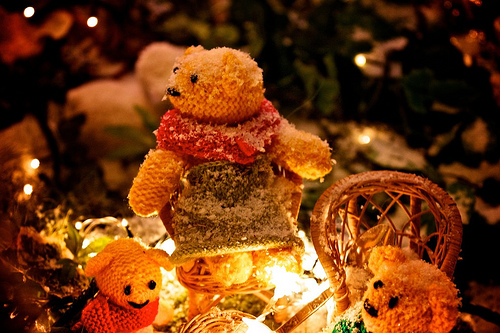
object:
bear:
[76, 239, 176, 332]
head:
[159, 44, 266, 123]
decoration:
[126, 42, 333, 294]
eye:
[173, 66, 179, 74]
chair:
[157, 170, 303, 325]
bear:
[60, 43, 185, 191]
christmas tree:
[269, 15, 499, 200]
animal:
[80, 45, 462, 332]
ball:
[164, 44, 265, 126]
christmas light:
[272, 258, 325, 305]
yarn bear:
[127, 45, 331, 284]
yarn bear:
[323, 244, 463, 333]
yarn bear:
[78, 237, 173, 333]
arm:
[128, 149, 183, 217]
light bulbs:
[22, 159, 42, 196]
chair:
[308, 169, 464, 317]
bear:
[362, 246, 464, 332]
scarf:
[73, 299, 160, 333]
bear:
[125, 44, 339, 285]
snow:
[161, 122, 265, 145]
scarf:
[153, 99, 281, 164]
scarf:
[330, 305, 369, 333]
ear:
[83, 249, 114, 276]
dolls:
[75, 44, 464, 332]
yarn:
[177, 72, 280, 244]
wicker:
[309, 171, 460, 300]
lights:
[20, 5, 102, 29]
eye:
[189, 74, 198, 83]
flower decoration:
[7, 181, 87, 331]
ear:
[146, 248, 175, 272]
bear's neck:
[100, 295, 159, 311]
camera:
[0, 0, 499, 333]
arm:
[269, 124, 337, 180]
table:
[2, 0, 500, 332]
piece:
[19, 52, 439, 332]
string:
[17, 8, 427, 70]